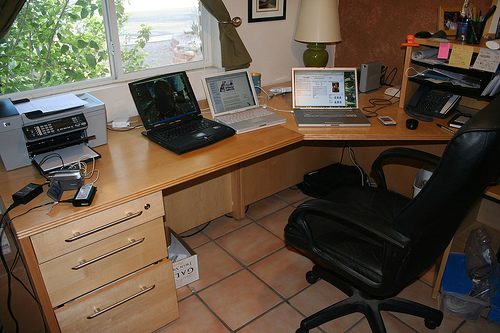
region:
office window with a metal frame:
[0, 0, 215, 100]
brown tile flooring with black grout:
[2, 181, 499, 331]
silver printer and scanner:
[1, 90, 109, 172]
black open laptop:
[127, 70, 236, 155]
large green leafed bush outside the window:
[0, 0, 154, 95]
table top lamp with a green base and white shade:
[293, 0, 343, 68]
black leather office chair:
[283, 95, 499, 331]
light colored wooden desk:
[1, 29, 499, 331]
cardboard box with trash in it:
[159, 225, 199, 289]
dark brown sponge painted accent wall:
[333, 0, 498, 90]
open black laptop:
[127, 70, 235, 154]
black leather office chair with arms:
[283, 101, 498, 331]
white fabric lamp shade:
[294, 0, 343, 42]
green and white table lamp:
[296, 0, 340, 68]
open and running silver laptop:
[291, 65, 370, 127]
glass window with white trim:
[0, 0, 214, 101]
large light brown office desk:
[1, 29, 498, 330]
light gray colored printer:
[0, 90, 109, 173]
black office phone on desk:
[404, 80, 459, 119]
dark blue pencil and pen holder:
[456, 18, 481, 45]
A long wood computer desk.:
[18, 89, 473, 329]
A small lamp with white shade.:
[287, 4, 351, 65]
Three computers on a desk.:
[121, 46, 396, 178]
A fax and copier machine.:
[6, 88, 117, 173]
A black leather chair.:
[280, 114, 499, 329]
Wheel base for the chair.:
[288, 267, 447, 331]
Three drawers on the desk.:
[20, 187, 191, 329]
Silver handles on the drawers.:
[51, 218, 163, 321]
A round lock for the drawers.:
[141, 198, 154, 212]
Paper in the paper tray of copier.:
[23, 142, 102, 169]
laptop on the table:
[119, 58, 238, 171]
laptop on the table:
[275, 59, 383, 142]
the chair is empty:
[292, 68, 498, 321]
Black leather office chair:
[282, 86, 499, 331]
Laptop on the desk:
[121, 69, 236, 164]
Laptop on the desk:
[191, 64, 286, 146]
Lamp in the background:
[287, 4, 350, 69]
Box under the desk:
[149, 219, 209, 296]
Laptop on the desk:
[280, 54, 377, 136]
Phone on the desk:
[405, 71, 466, 125]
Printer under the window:
[2, 89, 117, 171]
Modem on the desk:
[353, 49, 388, 99]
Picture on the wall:
[242, 0, 297, 36]